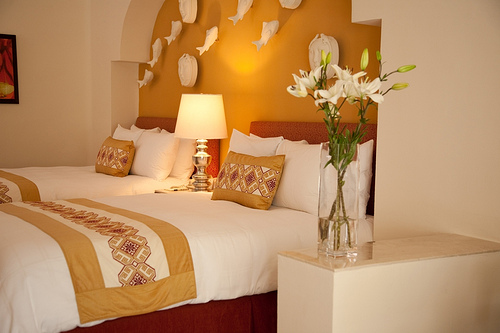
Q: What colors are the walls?
A: White and yellow.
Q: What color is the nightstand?
A: White.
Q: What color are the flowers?
A: White.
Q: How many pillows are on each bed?
A: Five.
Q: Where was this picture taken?
A: Bedroom.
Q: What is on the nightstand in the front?
A: A glass vase.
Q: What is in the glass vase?
A: Flowers.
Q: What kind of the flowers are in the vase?
A: Lilies.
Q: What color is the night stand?
A: Beige.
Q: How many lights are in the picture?
A: One.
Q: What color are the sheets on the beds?
A: White.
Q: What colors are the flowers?
A: White and green.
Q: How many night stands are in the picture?
A: Two.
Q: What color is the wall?
A: White.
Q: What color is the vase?
A: Clear.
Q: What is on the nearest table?
A: A vase.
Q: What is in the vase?
A: Flowers.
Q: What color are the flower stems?
A: Green.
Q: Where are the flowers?
A: In the vase.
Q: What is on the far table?
A: A lamp.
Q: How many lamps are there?
A: One.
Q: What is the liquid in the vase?
A: Water.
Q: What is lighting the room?
A: The lamp.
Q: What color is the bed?
A: White.